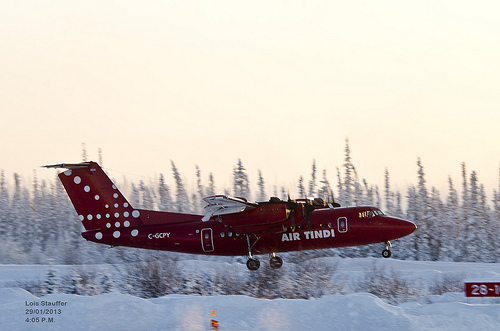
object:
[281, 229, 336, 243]
wording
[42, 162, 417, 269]
airplane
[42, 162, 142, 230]
tail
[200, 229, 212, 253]
door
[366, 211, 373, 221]
pilot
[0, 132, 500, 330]
snow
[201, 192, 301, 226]
wing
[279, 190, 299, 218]
propeller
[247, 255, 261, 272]
wheels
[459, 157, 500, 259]
trees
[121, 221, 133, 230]
dots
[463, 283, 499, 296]
sign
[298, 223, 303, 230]
light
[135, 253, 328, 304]
bushes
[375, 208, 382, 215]
windshield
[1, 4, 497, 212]
sky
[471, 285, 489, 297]
number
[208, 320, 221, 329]
flag